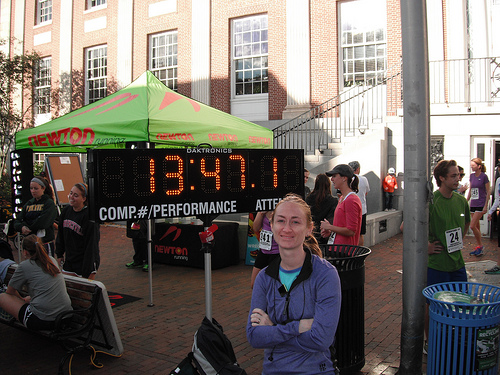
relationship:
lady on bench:
[3, 233, 75, 337] [6, 262, 113, 374]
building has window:
[0, 0, 500, 170] [228, 14, 269, 99]